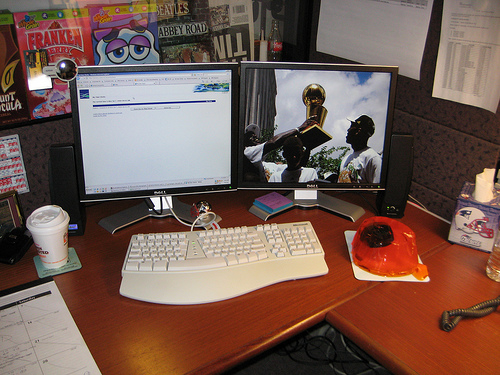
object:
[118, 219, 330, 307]
keyboard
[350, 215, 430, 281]
item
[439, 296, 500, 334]
cord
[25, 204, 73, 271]
cup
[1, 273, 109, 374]
calendar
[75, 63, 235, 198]
monitor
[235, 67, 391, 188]
monitor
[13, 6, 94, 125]
box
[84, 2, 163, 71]
box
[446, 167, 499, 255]
tissue box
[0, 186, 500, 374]
desk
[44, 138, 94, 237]
speaker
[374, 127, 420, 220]
speaker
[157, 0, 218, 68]
posters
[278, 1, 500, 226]
wall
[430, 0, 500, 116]
paper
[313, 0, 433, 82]
paper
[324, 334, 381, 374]
cords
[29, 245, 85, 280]
coaster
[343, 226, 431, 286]
mousepad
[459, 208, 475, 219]
logo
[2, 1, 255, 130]
display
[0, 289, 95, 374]
writing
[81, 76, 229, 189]
webpage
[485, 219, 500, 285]
bottle